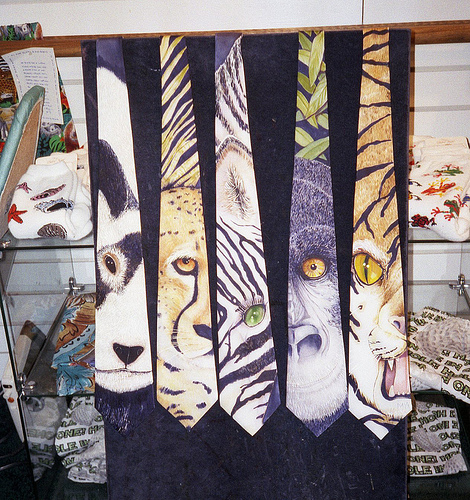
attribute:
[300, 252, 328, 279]
eye — orange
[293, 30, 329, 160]
leaves — green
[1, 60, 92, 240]
blanket — with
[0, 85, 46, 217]
board — leaning up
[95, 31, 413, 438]
ties — Five, colorful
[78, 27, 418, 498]
board — black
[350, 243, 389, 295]
eye — yellow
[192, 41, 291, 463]
tie — zebra, white, black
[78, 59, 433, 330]
ties — black, white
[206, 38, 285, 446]
zebra tie — black, white, striped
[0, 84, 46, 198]
cover — metallic, green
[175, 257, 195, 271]
eye — orange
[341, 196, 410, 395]
image — tiger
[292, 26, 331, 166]
leaf pattern — green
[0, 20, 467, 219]
bar — wooden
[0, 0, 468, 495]
wall — white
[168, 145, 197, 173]
stripe — black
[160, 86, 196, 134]
stripe — black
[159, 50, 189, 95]
stripe — black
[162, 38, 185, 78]
stripe — yellow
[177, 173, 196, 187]
stripe — yellow